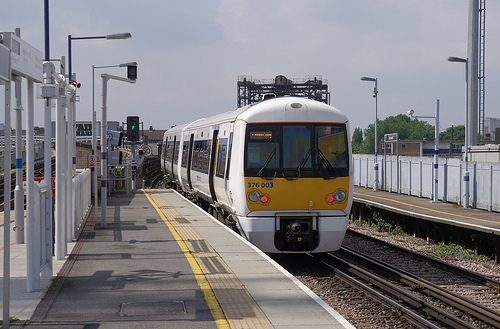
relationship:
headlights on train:
[242, 184, 368, 211] [101, 89, 354, 303]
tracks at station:
[322, 240, 441, 326] [14, 21, 206, 328]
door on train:
[203, 117, 220, 218] [101, 89, 354, 303]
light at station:
[123, 106, 153, 139] [14, 21, 206, 328]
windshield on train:
[245, 125, 346, 177] [101, 89, 354, 303]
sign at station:
[375, 121, 406, 149] [14, 21, 206, 328]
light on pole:
[123, 106, 153, 139] [126, 142, 155, 193]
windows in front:
[245, 125, 346, 177] [246, 94, 358, 248]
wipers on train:
[250, 136, 345, 190] [101, 89, 354, 303]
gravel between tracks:
[325, 268, 369, 328] [322, 240, 441, 326]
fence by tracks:
[368, 155, 493, 193] [322, 240, 441, 326]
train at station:
[101, 89, 354, 303] [14, 21, 206, 328]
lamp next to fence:
[398, 89, 441, 147] [368, 155, 493, 193]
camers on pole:
[118, 56, 147, 89] [89, 86, 117, 221]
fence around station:
[368, 155, 493, 193] [14, 21, 206, 328]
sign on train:
[242, 124, 277, 146] [101, 89, 354, 303]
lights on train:
[258, 189, 336, 214] [101, 89, 354, 303]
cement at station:
[105, 217, 209, 328] [14, 21, 206, 328]